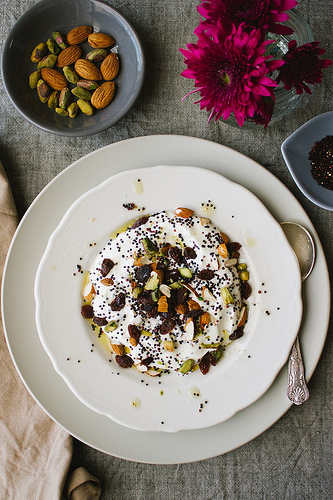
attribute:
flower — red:
[175, 20, 286, 129]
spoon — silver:
[270, 216, 321, 406]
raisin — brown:
[113, 290, 126, 310]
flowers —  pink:
[179, 17, 285, 126]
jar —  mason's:
[207, 7, 314, 131]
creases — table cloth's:
[143, 2, 205, 140]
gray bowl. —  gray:
[4, 2, 146, 132]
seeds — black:
[193, 392, 211, 411]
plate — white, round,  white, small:
[3, 133, 332, 468]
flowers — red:
[185, 1, 326, 120]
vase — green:
[203, 4, 312, 130]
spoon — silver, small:
[278, 219, 318, 405]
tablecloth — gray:
[1, 2, 332, 381]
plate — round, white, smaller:
[33, 167, 303, 429]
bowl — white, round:
[38, 166, 302, 427]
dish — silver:
[278, 109, 331, 210]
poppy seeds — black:
[310, 134, 330, 188]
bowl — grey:
[0, 4, 151, 145]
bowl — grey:
[6, 7, 147, 139]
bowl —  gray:
[279, 111, 331, 212]